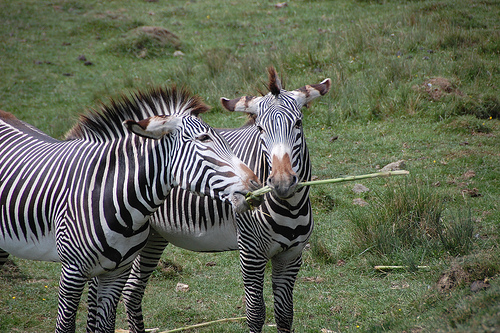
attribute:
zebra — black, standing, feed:
[0, 85, 263, 332]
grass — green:
[333, 38, 410, 116]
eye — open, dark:
[198, 135, 211, 142]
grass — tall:
[348, 177, 473, 257]